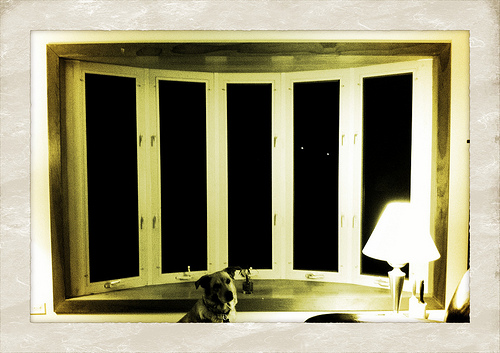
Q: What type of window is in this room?
A: Bay window.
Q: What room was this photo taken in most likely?
A: Living room.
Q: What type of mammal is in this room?
A: Dog.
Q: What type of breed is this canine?
A: Mixed breeds.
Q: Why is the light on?
A: Because it is night time.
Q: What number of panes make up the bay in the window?
A: 5.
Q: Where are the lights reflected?
A: In window.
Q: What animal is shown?
A: Dog.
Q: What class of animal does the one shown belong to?
A: Mammal.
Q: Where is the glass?
A: In windows.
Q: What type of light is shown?
A: Lamp.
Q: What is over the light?
A: Lampshade.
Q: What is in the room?
A: The lamp.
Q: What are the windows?
A: Close.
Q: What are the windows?
A: Close.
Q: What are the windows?
A: Close.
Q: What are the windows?
A: Close.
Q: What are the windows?
A: Close.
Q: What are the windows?
A: Close.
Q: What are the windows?
A: Close.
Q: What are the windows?
A: Close.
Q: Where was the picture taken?
A: In a house.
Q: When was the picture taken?
A: Nighttime.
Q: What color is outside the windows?
A: Black.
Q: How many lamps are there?
A: One.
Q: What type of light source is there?
A: A lamp.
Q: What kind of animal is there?
A: A dog.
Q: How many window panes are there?
A: Five.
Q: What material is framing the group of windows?
A: Wood.